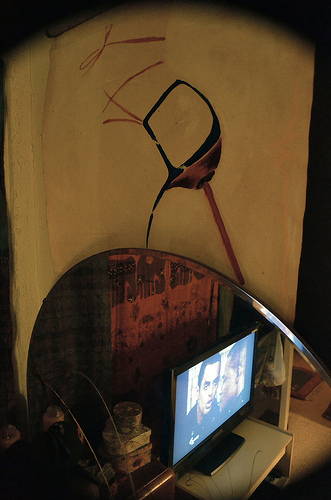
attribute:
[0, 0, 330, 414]
wall — white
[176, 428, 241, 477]
tv stand — black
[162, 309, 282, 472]
tv — flat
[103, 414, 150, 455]
gift box — heart shaped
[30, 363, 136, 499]
wires — twisted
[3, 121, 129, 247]
wall — white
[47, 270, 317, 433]
shaped mirror — round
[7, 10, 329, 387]
wall — white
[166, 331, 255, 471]
tv — on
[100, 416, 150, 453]
box — heart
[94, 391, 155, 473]
boxes — paper 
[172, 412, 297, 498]
table top — white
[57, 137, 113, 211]
wall — white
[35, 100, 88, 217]
wall — white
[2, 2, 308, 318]
wall — white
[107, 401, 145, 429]
boxes — three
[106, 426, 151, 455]
box — round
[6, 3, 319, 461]
wall — white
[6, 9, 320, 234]
wall — white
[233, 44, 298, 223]
wall — white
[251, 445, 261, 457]
table — wood, white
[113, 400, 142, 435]
gift box — circular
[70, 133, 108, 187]
wall — white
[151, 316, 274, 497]
tv — on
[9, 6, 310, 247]
wall — white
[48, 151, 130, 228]
wall — white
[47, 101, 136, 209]
wall — white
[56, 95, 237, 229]
wall — white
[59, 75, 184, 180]
wall — white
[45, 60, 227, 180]
wall — white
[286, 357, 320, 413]
mat — welcome